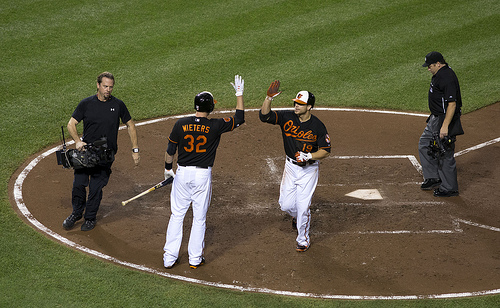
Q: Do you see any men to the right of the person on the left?
A: Yes, there is a man to the right of the person.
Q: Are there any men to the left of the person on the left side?
A: No, the man is to the right of the person.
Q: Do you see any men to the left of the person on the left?
A: No, the man is to the right of the person.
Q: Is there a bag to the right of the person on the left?
A: No, there is a man to the right of the person.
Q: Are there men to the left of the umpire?
A: Yes, there is a man to the left of the umpire.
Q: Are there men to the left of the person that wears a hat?
A: Yes, there is a man to the left of the umpire.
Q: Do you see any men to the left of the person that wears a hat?
A: Yes, there is a man to the left of the umpire.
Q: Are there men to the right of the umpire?
A: No, the man is to the left of the umpire.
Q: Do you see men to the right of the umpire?
A: No, the man is to the left of the umpire.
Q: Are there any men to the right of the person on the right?
A: No, the man is to the left of the umpire.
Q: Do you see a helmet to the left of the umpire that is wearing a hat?
A: No, there is a man to the left of the umpire.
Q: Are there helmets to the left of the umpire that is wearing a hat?
A: No, there is a man to the left of the umpire.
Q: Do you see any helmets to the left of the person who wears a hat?
A: No, there is a man to the left of the umpire.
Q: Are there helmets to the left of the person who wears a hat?
A: No, there is a man to the left of the umpire.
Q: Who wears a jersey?
A: The man wears a jersey.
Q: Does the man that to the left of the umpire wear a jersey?
A: Yes, the man wears a jersey.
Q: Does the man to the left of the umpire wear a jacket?
A: No, the man wears a jersey.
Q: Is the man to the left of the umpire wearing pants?
A: Yes, the man is wearing pants.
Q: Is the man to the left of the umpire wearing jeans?
A: No, the man is wearing pants.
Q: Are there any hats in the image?
A: Yes, there is a hat.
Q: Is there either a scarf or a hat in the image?
A: Yes, there is a hat.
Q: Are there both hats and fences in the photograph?
A: No, there is a hat but no fences.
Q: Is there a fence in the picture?
A: No, there are no fences.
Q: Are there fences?
A: No, there are no fences.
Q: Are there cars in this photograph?
A: No, there are no cars.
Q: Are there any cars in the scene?
A: No, there are no cars.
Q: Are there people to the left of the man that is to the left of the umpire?
A: Yes, there is a person to the left of the man.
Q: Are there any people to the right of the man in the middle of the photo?
A: No, the person is to the left of the man.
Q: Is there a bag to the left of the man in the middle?
A: No, there is a person to the left of the man.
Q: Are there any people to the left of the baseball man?
A: Yes, there is a person to the left of the man.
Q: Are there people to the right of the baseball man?
A: No, the person is to the left of the man.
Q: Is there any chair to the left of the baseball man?
A: No, there is a person to the left of the man.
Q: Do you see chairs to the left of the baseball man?
A: No, there is a person to the left of the man.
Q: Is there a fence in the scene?
A: No, there are no fences.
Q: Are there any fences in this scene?
A: No, there are no fences.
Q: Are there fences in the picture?
A: No, there are no fences.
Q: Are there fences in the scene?
A: No, there are no fences.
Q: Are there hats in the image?
A: Yes, there is a hat.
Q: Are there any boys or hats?
A: Yes, there is a hat.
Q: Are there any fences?
A: No, there are no fences.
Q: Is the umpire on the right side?
A: Yes, the umpire is on the right of the image.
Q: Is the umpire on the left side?
A: No, the umpire is on the right of the image.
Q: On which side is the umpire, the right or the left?
A: The umpire is on the right of the image.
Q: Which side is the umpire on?
A: The umpire is on the right of the image.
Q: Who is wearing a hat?
A: The umpire is wearing a hat.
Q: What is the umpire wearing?
A: The umpire is wearing a hat.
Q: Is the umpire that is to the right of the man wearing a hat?
A: Yes, the umpire is wearing a hat.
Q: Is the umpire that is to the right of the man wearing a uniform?
A: No, the umpire is wearing a hat.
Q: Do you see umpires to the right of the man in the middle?
A: Yes, there is an umpire to the right of the man.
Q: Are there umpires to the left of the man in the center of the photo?
A: No, the umpire is to the right of the man.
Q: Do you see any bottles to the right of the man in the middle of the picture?
A: No, there is an umpire to the right of the man.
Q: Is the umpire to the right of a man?
A: Yes, the umpire is to the right of a man.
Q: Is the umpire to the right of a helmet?
A: No, the umpire is to the right of a man.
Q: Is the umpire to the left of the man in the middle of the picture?
A: No, the umpire is to the right of the man.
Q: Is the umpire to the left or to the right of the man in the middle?
A: The umpire is to the right of the man.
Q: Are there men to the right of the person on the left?
A: Yes, there is a man to the right of the person.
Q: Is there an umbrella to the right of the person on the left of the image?
A: No, there is a man to the right of the person.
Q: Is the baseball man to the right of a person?
A: Yes, the man is to the right of a person.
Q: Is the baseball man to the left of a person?
A: No, the man is to the right of a person.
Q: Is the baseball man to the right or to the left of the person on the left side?
A: The man is to the right of the person.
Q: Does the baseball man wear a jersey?
A: Yes, the man wears a jersey.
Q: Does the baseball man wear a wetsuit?
A: No, the man wears a jersey.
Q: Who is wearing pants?
A: The man is wearing pants.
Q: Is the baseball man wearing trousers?
A: Yes, the man is wearing trousers.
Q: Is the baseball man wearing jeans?
A: No, the man is wearing trousers.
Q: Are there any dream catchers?
A: No, there are no dream catchers.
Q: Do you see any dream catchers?
A: No, there are no dream catchers.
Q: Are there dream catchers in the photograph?
A: No, there are no dream catchers.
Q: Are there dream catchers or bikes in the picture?
A: No, there are no dream catchers or bikes.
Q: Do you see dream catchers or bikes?
A: No, there are no dream catchers or bikes.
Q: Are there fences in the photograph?
A: No, there are no fences.